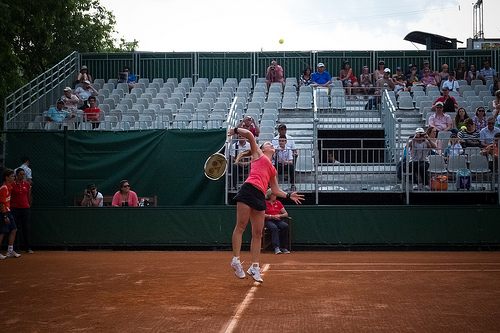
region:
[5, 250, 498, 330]
clay and white lines covering tennis court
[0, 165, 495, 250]
two people by green material of partition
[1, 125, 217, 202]
two people seated in area with green wall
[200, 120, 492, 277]
player and seated woman on court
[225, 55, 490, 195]
gray railing in front of spectators and empty seats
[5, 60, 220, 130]
some people in rows of seating above green wall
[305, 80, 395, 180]
railing around sides of dark passageway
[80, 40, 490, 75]
railing and opaque fabric on back wall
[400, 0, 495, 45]
slanted dark structure by wire columns on base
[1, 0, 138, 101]
large tree higher than corner of stadium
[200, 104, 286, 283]
the woman on the court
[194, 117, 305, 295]
the woman swinging the racquet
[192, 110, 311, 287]
the woman playing tennis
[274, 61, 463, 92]
people in the stands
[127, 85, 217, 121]
empty seats in the stands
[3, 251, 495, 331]
the court is clay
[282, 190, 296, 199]
the band on the wrist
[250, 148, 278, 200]
the woman wearing pink top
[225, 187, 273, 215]
the woman wearing black skirt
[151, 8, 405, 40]
the sky is blue and clear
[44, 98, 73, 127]
person watching tennis match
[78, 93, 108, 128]
person watching tennis match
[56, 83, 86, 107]
person watching tennis match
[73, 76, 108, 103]
person watching tennis match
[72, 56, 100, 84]
person watching tennis match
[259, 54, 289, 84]
person watching tennis match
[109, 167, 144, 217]
person watching tennis match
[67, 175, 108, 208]
person watching tennis match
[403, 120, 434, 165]
person watching tennis match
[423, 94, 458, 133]
person watching tennis match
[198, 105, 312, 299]
A tennis player in the mid-jump.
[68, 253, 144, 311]
the court is brown.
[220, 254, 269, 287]
The player is wearing white tennis shoes.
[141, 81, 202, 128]
Empty white chairs in the bleachers.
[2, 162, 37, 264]
Two spectators on the field.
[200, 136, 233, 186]
A large tennis racket in the players hand.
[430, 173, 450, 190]
A small light brown bag on the floor.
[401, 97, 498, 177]
Several people watch with disinterest.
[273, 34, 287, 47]
A tennis ball sails through the air.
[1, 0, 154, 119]
A large tree overlooks the field.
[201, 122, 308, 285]
A woman is playing tennis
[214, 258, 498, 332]
White lines on the court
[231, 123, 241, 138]
A black arm band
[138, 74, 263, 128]
Many empty white seats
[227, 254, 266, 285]
A pair of white sneakers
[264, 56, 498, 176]
Spectators are watching the tennis game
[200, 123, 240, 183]
A tennis racket in a hand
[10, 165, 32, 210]
A person wearing a red shirt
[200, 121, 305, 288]
The tennis player is jumping up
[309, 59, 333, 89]
Man wearing a blue shirt